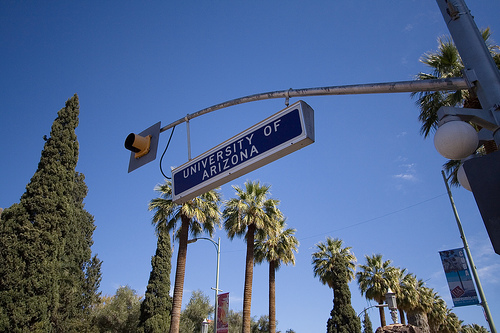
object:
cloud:
[361, 143, 420, 187]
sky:
[0, 3, 498, 310]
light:
[123, 120, 158, 174]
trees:
[0, 91, 116, 332]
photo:
[0, 0, 499, 331]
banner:
[435, 244, 480, 310]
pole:
[440, 166, 500, 332]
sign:
[164, 99, 315, 204]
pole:
[150, 75, 488, 129]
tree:
[224, 177, 276, 332]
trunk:
[240, 233, 256, 333]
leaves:
[242, 215, 254, 227]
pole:
[214, 238, 220, 332]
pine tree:
[141, 204, 179, 333]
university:
[173, 134, 258, 179]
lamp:
[433, 118, 478, 161]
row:
[173, 269, 393, 304]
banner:
[214, 292, 232, 332]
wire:
[156, 121, 177, 181]